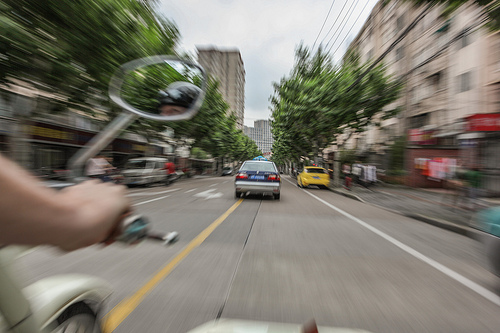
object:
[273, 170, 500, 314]
line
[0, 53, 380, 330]
scooter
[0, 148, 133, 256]
rider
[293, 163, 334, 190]
taxi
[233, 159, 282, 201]
car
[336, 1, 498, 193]
building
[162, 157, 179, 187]
person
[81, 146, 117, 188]
person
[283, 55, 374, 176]
trees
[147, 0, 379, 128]
sky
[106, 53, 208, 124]
mirror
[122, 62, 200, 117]
reflection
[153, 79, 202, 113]
helmet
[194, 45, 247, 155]
building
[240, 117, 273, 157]
building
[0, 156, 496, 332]
street